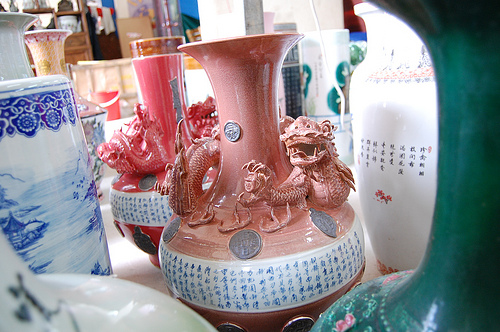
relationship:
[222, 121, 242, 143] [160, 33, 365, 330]
coin on vase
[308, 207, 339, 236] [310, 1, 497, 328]
coin on vase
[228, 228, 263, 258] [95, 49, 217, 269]
coin on vase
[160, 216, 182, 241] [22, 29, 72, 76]
coin on vase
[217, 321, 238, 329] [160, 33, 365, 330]
coin on vase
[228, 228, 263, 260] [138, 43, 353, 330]
coin on vase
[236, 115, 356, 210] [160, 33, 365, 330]
dragon on vase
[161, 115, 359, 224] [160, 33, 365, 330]
dragon on vase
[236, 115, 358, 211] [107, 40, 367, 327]
dragon on vase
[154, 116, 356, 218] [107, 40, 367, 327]
dragon on vase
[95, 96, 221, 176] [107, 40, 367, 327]
dragon on vase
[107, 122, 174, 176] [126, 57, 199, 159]
dragon on vase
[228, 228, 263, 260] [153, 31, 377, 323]
coin on vase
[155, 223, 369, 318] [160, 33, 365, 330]
lettering on vase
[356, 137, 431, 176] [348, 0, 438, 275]
writing on vase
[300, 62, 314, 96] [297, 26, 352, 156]
green flower on white vase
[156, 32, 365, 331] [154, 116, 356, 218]
ceramic vase with dragon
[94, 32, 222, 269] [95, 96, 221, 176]
red vase with dragon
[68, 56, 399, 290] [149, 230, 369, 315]
vase with lettering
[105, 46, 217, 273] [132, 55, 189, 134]
vase with neck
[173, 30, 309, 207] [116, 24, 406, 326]
neck with vase